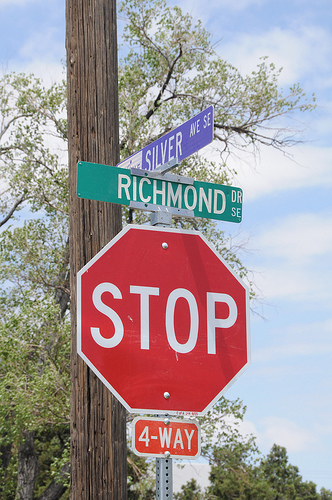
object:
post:
[153, 459, 173, 498]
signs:
[117, 108, 213, 172]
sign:
[131, 420, 200, 456]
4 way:
[136, 420, 195, 448]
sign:
[76, 216, 247, 415]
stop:
[90, 281, 234, 358]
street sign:
[76, 155, 244, 221]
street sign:
[113, 101, 214, 176]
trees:
[0, 72, 69, 439]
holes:
[165, 472, 170, 478]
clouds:
[245, 210, 332, 261]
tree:
[0, 0, 318, 500]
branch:
[223, 115, 314, 171]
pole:
[66, 0, 127, 500]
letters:
[130, 286, 159, 352]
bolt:
[161, 242, 168, 248]